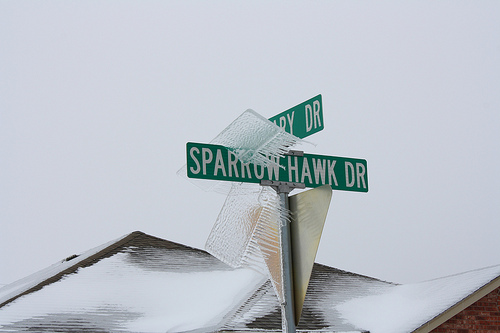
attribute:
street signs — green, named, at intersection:
[137, 108, 379, 241]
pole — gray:
[278, 279, 307, 305]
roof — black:
[124, 231, 168, 248]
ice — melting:
[227, 111, 301, 156]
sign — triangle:
[223, 200, 320, 302]